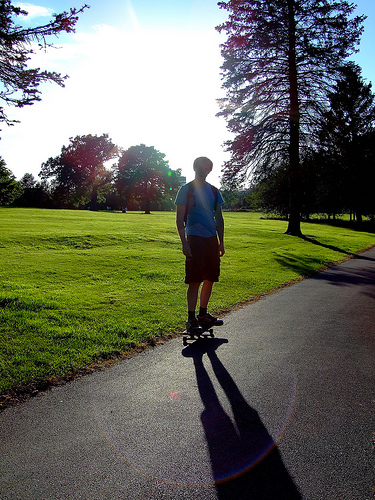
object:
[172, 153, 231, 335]
man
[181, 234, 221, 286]
shorts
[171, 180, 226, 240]
shirt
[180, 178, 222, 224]
backpack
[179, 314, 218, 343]
skateboard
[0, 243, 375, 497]
path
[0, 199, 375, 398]
grass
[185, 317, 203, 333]
shoes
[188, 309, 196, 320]
socks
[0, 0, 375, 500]
park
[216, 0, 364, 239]
tree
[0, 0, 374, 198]
sky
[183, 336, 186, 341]
wheel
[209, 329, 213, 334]
wheel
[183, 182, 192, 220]
straps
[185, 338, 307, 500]
shadow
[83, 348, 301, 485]
light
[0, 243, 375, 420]
edge